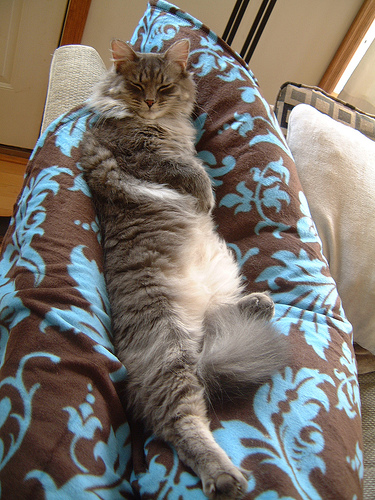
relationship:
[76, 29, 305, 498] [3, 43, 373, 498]
cat on couch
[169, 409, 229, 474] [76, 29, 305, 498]
cat's leg of cat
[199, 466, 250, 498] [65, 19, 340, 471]
paw of cat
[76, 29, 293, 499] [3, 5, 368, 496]
cat on blanket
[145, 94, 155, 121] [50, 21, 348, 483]
nose on cat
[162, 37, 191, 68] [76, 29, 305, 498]
ear on cat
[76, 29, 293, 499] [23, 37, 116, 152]
cat on couch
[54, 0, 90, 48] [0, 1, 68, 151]
wood trim on door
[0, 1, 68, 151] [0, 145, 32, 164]
door with wood trim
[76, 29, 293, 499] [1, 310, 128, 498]
cat on blanket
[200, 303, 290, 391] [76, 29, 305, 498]
tail on cat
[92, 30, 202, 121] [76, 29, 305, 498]
head on cat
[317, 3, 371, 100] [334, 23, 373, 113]
frame of window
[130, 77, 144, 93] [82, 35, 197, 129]
eye of cat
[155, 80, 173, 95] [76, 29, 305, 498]
eye of cat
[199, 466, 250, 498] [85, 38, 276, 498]
paw of cat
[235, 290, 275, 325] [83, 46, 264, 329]
paw of cat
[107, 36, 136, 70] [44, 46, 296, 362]
ear of cat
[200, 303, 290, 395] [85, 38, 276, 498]
tail of cat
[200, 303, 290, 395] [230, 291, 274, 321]
tail between cat's leg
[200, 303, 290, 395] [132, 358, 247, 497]
tail between cat's leg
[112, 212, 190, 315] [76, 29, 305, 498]
fur on cat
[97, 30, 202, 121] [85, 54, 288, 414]
head of cat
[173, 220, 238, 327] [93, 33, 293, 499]
fur on cat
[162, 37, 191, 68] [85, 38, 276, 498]
ear on cat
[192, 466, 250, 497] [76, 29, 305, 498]
paw of cat